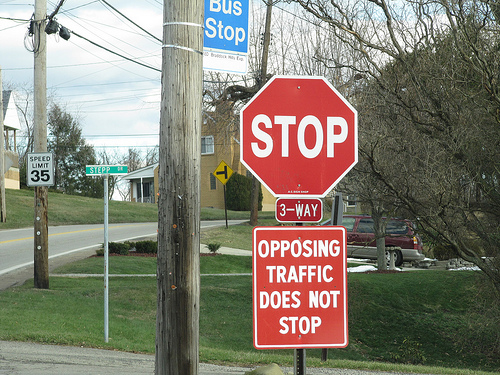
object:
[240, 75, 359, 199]
sign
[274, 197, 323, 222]
sign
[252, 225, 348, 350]
sign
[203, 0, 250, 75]
sign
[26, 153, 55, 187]
sign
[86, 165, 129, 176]
sign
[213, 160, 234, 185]
sign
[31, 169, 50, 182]
number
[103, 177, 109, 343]
post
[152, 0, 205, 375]
pole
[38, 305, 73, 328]
grass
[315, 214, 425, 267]
suv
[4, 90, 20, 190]
building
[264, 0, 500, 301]
tree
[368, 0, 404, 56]
branch